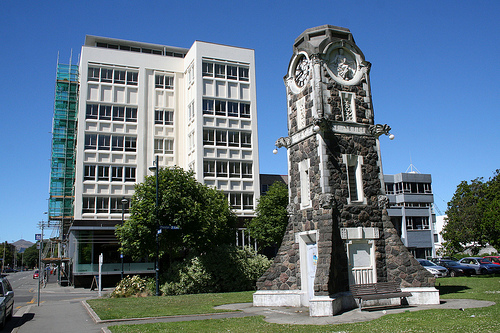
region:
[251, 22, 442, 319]
A small stone clock tower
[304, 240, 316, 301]
A white door on the tower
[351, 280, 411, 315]
A wooden bench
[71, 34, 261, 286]
A large white building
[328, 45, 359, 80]
A statue on the tower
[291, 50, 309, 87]
A clock on the tower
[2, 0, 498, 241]
A clear blue sky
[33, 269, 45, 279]
A parked red car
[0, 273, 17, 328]
A parked car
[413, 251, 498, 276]
A row of parked cars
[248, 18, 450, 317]
large monument made of stone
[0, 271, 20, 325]
vehicle parked on the street near the monument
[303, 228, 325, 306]
white door of the monument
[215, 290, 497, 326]
cement sidewalk around the monument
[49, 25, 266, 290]
tallest building in the area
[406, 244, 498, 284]
cars parked in a lot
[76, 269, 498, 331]
grassy area near the monument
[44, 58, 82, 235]
green fire escape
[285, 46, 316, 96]
clock face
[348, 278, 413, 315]
wooden bench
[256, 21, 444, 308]
a tower in a park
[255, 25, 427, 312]
a stone tower in a park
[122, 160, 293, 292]
leafy green trees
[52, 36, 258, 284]
a white building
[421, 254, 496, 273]
cars in a parking lot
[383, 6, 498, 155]
a clear blue sky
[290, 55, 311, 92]
a clock on the tower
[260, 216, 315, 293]
stone walls on a tower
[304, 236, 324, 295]
a white door on the tower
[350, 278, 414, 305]
a gray bench by the tower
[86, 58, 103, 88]
a window on the building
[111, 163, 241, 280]
a leafy green tree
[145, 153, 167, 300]
a large metal pole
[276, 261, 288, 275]
a rock on the pillar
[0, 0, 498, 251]
a clear blue sky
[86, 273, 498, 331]
a grassy green field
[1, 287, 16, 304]
a side view mirror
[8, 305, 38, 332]
a shadow on the ground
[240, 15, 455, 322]
a large stone pillar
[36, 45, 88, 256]
a scaffold on the building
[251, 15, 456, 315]
tower with clock on ground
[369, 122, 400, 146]
light hanging off tower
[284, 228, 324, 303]
door on side of tower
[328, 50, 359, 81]
figure on face of tower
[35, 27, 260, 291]
building in background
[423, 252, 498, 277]
vehicles in front of building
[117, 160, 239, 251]
top of tree near tower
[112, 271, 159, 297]
patch of flowers on ground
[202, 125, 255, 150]
panel of windows on building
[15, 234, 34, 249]
top of mountain in near back